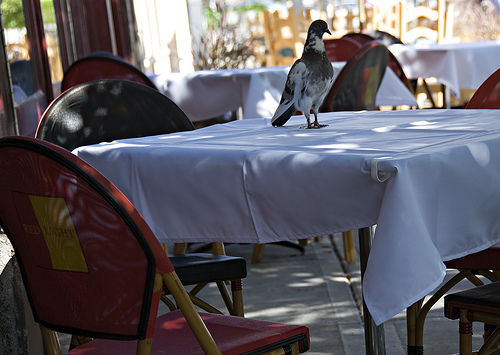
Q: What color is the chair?
A: Red and yellow.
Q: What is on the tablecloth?
A: Bird.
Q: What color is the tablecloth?
A: White.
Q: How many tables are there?
A: 3.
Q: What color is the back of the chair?
A: Red.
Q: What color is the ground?
A: Gray.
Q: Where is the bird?
A: On the table.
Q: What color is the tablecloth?
A: White.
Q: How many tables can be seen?
A: Three.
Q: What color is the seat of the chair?
A: Red.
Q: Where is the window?
A: On the building.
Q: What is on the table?
A: A bird.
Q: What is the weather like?
A: Sunny.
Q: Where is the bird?
A: On table.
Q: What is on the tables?
A: Tablecloths.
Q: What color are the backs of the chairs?
A: Red.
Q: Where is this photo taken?
A: Restaurant patio.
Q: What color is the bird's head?
A: Gray.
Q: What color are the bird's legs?
A: White.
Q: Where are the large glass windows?
A: Left.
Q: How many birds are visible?
A: 1.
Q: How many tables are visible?
A: 3.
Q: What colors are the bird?
A: Gray and white.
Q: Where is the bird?
A: On table.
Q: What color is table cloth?
A: White.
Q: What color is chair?
A: Red.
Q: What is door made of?
A: Glass.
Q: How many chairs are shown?
A: Seven.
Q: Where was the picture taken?
A: Restaurant.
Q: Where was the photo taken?
A: At a sidewalk cafe.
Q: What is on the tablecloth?
A: A bird.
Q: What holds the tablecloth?
A: A clip.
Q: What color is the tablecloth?
A: White.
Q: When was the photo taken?
A: Daytime.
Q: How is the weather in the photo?
A: Bright and sunny.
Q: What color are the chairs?
A: Red and black.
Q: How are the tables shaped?
A: Square.